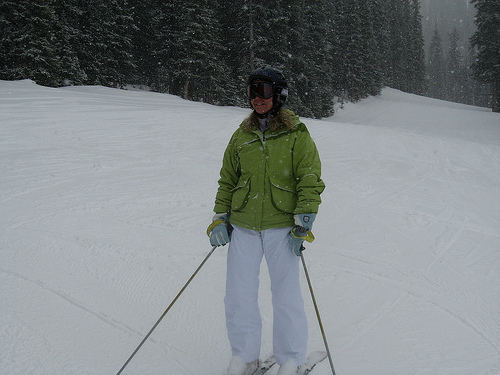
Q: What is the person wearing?
A: A coat.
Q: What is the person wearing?
A: White pants.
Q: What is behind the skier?
A: Pine trees.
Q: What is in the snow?
A: Ski tracks.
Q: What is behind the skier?
A: White slope.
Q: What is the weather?
A: Winter day.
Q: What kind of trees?
A: Evergreen.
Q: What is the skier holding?
A: Ski poles.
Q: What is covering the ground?
A: Snow.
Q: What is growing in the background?
A: Trees.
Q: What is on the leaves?
A: Snow.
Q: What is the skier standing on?
A: Skis.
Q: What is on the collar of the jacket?
A: Fur.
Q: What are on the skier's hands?
A: Gloves.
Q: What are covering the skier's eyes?
A: Goggles.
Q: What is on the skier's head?
A: Helmet.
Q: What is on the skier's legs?
A: Pants.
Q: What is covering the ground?
A: Snow.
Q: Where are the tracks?
A: In the snow.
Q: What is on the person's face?
A: Goggles.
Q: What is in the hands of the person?
A: Ski poles.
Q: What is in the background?
A: Trees.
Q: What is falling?
A: Snow.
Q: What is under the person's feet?
A: Skis.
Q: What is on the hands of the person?
A: Gloves.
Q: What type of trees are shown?
A: Pine trees.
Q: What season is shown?
A: Winter.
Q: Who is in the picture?
A: A female skier.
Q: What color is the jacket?
A: Green.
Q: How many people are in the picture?
A: One.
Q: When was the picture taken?
A: During the day.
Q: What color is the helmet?
A: Black.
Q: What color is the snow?
A: White.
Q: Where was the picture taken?
A: On a ski slope.